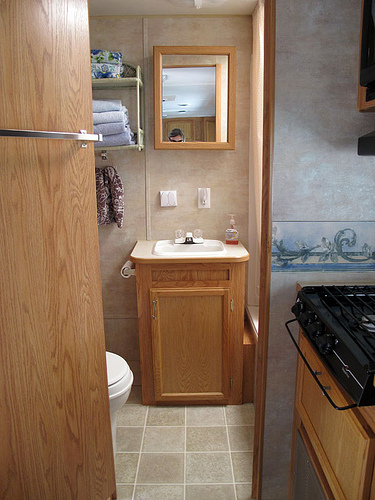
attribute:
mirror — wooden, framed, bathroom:
[148, 41, 235, 151]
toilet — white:
[106, 347, 134, 459]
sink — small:
[151, 227, 227, 259]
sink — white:
[150, 225, 229, 258]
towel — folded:
[92, 96, 122, 112]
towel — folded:
[92, 109, 128, 126]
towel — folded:
[88, 119, 131, 135]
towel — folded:
[95, 129, 135, 148]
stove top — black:
[288, 277, 373, 412]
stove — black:
[281, 279, 373, 414]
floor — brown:
[114, 383, 254, 494]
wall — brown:
[86, 13, 249, 385]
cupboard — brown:
[146, 283, 233, 405]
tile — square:
[182, 405, 227, 428]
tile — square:
[183, 424, 228, 456]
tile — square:
[180, 449, 233, 487]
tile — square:
[137, 424, 187, 457]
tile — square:
[132, 449, 187, 487]